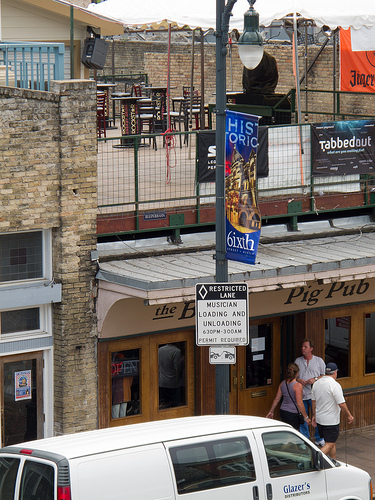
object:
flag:
[223, 111, 265, 264]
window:
[262, 432, 329, 477]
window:
[168, 435, 256, 499]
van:
[0, 412, 375, 500]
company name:
[284, 482, 311, 494]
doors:
[99, 328, 201, 430]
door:
[230, 310, 309, 428]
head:
[325, 363, 339, 382]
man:
[293, 339, 326, 447]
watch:
[314, 376, 318, 381]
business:
[92, 225, 375, 459]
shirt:
[310, 375, 346, 426]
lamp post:
[212, 0, 231, 415]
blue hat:
[326, 362, 340, 372]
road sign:
[194, 283, 251, 365]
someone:
[112, 350, 137, 419]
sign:
[109, 347, 140, 420]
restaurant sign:
[285, 278, 371, 307]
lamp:
[234, 0, 263, 75]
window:
[1, 226, 53, 286]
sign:
[222, 110, 264, 266]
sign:
[310, 119, 375, 174]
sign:
[339, 23, 375, 94]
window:
[107, 342, 143, 421]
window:
[157, 333, 190, 413]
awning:
[96, 215, 375, 338]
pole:
[214, 0, 232, 414]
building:
[0, 0, 375, 452]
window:
[0, 304, 42, 339]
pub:
[97, 212, 374, 459]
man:
[311, 361, 354, 460]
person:
[265, 362, 312, 433]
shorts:
[318, 421, 339, 443]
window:
[246, 321, 273, 391]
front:
[102, 215, 375, 432]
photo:
[2, 0, 375, 500]